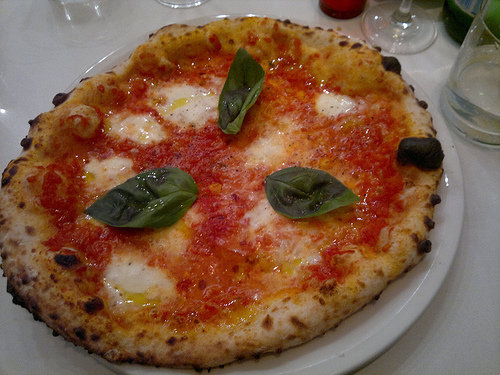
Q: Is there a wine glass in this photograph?
A: Yes, there is a wine glass.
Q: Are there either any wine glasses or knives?
A: Yes, there is a wine glass.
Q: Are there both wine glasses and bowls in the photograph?
A: No, there is a wine glass but no bowls.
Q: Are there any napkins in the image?
A: No, there are no napkins.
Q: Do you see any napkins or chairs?
A: No, there are no napkins or chairs.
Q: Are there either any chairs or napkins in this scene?
A: No, there are no napkins or chairs.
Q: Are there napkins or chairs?
A: No, there are no napkins or chairs.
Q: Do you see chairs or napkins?
A: No, there are no napkins or chairs.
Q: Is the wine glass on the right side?
A: Yes, the wine glass is on the right of the image.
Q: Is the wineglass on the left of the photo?
A: No, the wineglass is on the right of the image.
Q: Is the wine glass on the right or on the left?
A: The wine glass is on the right of the image.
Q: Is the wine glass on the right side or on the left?
A: The wine glass is on the right of the image.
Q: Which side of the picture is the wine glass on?
A: The wine glass is on the right of the image.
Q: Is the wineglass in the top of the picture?
A: Yes, the wineglass is in the top of the image.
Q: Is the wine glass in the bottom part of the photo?
A: No, the wine glass is in the top of the image.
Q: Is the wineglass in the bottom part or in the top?
A: The wineglass is in the top of the image.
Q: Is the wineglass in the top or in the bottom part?
A: The wineglass is in the top of the image.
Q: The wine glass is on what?
A: The wine glass is on the table.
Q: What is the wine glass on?
A: The wine glass is on the table.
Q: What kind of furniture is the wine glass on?
A: The wine glass is on the table.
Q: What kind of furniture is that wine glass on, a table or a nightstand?
A: The wine glass is on a table.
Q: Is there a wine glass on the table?
A: Yes, there is a wine glass on the table.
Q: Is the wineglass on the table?
A: Yes, the wineglass is on the table.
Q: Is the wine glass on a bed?
A: No, the wine glass is on the table.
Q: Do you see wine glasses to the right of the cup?
A: Yes, there is a wine glass to the right of the cup.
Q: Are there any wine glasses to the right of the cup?
A: Yes, there is a wine glass to the right of the cup.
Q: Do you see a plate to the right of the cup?
A: No, there is a wine glass to the right of the cup.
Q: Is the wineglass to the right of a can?
A: No, the wineglass is to the right of the cup.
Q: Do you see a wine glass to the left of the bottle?
A: Yes, there is a wine glass to the left of the bottle.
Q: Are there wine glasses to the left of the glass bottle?
A: Yes, there is a wine glass to the left of the bottle.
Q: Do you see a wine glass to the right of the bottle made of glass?
A: No, the wine glass is to the left of the bottle.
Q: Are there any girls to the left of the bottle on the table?
A: No, there is a wine glass to the left of the bottle.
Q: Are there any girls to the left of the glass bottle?
A: No, there is a wine glass to the left of the bottle.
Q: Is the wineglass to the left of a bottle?
A: Yes, the wineglass is to the left of a bottle.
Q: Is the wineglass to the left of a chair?
A: No, the wineglass is to the left of a bottle.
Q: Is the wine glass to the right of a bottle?
A: No, the wine glass is to the left of a bottle.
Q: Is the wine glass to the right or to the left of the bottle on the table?
A: The wine glass is to the left of the bottle.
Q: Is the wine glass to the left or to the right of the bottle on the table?
A: The wine glass is to the left of the bottle.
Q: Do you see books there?
A: No, there are no books.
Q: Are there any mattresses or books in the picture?
A: No, there are no books or mattresses.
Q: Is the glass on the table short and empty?
A: Yes, the glass is short and empty.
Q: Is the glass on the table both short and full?
A: No, the glass is short but empty.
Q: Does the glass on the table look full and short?
A: No, the glass is short but empty.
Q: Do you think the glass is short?
A: Yes, the glass is short.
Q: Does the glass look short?
A: Yes, the glass is short.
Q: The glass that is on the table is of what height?
A: The glass is short.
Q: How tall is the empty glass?
A: The glass is short.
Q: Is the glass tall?
A: No, the glass is short.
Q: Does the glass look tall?
A: No, the glass is short.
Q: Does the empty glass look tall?
A: No, the glass is short.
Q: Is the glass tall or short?
A: The glass is short.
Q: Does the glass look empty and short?
A: Yes, the glass is empty and short.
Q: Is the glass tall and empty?
A: No, the glass is empty but short.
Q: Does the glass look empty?
A: Yes, the glass is empty.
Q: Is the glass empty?
A: Yes, the glass is empty.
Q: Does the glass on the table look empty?
A: Yes, the glass is empty.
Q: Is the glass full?
A: No, the glass is empty.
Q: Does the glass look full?
A: No, the glass is empty.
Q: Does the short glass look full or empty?
A: The glass is empty.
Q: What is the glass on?
A: The glass is on the table.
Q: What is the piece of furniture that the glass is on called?
A: The piece of furniture is a table.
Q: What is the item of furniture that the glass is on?
A: The piece of furniture is a table.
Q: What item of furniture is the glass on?
A: The glass is on the table.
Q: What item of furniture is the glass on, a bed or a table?
A: The glass is on a table.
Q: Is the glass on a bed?
A: No, the glass is on the table.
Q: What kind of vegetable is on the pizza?
A: The vegetable is spinach.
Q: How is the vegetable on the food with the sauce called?
A: The vegetable is spinach.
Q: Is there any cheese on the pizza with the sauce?
A: No, there is spinach on the pizza.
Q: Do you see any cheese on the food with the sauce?
A: No, there is spinach on the pizza.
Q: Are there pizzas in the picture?
A: Yes, there is a pizza.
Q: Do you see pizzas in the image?
A: Yes, there is a pizza.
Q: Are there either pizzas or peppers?
A: Yes, there is a pizza.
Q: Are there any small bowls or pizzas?
A: Yes, there is a small pizza.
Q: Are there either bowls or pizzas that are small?
A: Yes, the pizza is small.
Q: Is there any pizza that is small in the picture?
A: Yes, there is a small pizza.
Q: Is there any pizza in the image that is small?
A: Yes, there is a pizza that is small.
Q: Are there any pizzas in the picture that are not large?
A: Yes, there is a small pizza.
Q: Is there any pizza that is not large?
A: Yes, there is a small pizza.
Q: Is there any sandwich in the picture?
A: No, there are no sandwiches.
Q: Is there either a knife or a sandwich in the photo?
A: No, there are no sandwiches or knives.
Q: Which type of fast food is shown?
A: The fast food is a pizza.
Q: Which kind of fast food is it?
A: The food is a pizza.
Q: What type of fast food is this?
A: This is a pizza.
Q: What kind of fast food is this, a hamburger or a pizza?
A: This is a pizza.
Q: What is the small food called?
A: The food is a pizza.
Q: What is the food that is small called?
A: The food is a pizza.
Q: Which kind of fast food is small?
A: The fast food is a pizza.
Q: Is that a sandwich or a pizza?
A: That is a pizza.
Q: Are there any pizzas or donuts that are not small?
A: No, there is a pizza but it is small.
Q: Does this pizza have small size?
A: Yes, the pizza is small.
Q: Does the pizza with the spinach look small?
A: Yes, the pizza is small.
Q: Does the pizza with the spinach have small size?
A: Yes, the pizza is small.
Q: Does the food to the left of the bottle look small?
A: Yes, the pizza is small.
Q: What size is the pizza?
A: The pizza is small.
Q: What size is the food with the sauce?
A: The pizza is small.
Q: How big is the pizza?
A: The pizza is small.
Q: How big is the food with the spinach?
A: The pizza is small.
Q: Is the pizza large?
A: No, the pizza is small.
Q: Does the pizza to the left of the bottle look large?
A: No, the pizza is small.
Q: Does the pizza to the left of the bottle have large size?
A: No, the pizza is small.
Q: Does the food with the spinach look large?
A: No, the pizza is small.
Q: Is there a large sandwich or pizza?
A: No, there is a pizza but it is small.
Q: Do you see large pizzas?
A: No, there is a pizza but it is small.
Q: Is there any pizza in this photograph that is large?
A: No, there is a pizza but it is small.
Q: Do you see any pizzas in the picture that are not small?
A: No, there is a pizza but it is small.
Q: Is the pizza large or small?
A: The pizza is small.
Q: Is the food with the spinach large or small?
A: The pizza is small.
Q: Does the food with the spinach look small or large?
A: The pizza is small.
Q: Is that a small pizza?
A: Yes, that is a small pizza.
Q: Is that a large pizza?
A: No, that is a small pizza.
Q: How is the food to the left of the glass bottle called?
A: The food is a pizza.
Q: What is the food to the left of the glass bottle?
A: The food is a pizza.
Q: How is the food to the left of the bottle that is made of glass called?
A: The food is a pizza.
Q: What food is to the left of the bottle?
A: The food is a pizza.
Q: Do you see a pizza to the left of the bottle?
A: Yes, there is a pizza to the left of the bottle.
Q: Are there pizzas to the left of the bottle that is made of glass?
A: Yes, there is a pizza to the left of the bottle.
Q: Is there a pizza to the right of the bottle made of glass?
A: No, the pizza is to the left of the bottle.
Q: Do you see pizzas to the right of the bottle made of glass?
A: No, the pizza is to the left of the bottle.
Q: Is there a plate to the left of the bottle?
A: No, there is a pizza to the left of the bottle.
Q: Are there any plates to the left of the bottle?
A: No, there is a pizza to the left of the bottle.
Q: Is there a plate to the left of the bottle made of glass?
A: No, there is a pizza to the left of the bottle.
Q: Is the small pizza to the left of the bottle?
A: Yes, the pizza is to the left of the bottle.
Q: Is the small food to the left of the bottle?
A: Yes, the pizza is to the left of the bottle.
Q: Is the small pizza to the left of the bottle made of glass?
A: Yes, the pizza is to the left of the bottle.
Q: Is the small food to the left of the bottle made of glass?
A: Yes, the pizza is to the left of the bottle.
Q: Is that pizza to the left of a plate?
A: No, the pizza is to the left of the bottle.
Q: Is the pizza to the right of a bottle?
A: No, the pizza is to the left of a bottle.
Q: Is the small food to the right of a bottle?
A: No, the pizza is to the left of a bottle.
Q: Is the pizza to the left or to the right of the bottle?
A: The pizza is to the left of the bottle.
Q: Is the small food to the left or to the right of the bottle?
A: The pizza is to the left of the bottle.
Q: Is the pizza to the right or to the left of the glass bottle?
A: The pizza is to the left of the bottle.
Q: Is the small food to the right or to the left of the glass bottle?
A: The pizza is to the left of the bottle.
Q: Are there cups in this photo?
A: Yes, there is a cup.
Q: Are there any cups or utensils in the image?
A: Yes, there is a cup.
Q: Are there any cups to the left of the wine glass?
A: Yes, there is a cup to the left of the wine glass.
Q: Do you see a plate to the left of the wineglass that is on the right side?
A: No, there is a cup to the left of the wine glass.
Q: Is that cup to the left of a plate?
A: No, the cup is to the left of the wine glass.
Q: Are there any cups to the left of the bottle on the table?
A: Yes, there is a cup to the left of the bottle.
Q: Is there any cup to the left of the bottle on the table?
A: Yes, there is a cup to the left of the bottle.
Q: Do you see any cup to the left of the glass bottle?
A: Yes, there is a cup to the left of the bottle.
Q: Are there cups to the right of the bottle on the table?
A: No, the cup is to the left of the bottle.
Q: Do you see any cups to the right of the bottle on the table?
A: No, the cup is to the left of the bottle.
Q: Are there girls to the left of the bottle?
A: No, there is a cup to the left of the bottle.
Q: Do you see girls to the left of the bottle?
A: No, there is a cup to the left of the bottle.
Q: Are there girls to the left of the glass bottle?
A: No, there is a cup to the left of the bottle.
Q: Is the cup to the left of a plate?
A: No, the cup is to the left of the bottle.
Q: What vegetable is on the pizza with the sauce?
A: The vegetable is spinach.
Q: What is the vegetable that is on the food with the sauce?
A: The vegetable is spinach.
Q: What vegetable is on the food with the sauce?
A: The vegetable is spinach.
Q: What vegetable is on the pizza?
A: The vegetable is spinach.